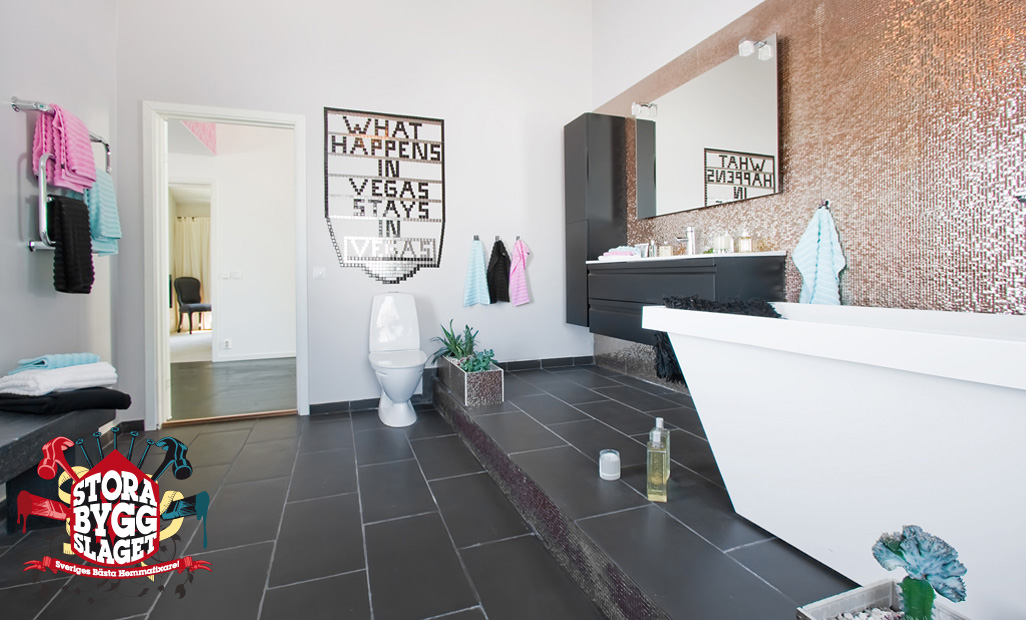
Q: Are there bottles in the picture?
A: Yes, there is a bottle.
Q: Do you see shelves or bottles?
A: Yes, there is a bottle.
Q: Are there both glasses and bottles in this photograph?
A: No, there is a bottle but no glasses.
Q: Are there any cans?
A: No, there are no cans.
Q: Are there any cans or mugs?
A: No, there are no cans or mugs.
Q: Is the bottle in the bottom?
A: Yes, the bottle is in the bottom of the image.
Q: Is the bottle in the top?
A: No, the bottle is in the bottom of the image.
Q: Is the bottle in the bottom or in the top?
A: The bottle is in the bottom of the image.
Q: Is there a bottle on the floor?
A: Yes, there is a bottle on the floor.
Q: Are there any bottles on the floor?
A: Yes, there is a bottle on the floor.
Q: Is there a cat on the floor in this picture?
A: No, there is a bottle on the floor.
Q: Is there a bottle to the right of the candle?
A: Yes, there is a bottle to the right of the candle.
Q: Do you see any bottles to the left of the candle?
A: No, the bottle is to the right of the candle.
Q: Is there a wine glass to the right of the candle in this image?
A: No, there is a bottle to the right of the candle.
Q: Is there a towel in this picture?
A: Yes, there is a towel.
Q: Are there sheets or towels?
A: Yes, there is a towel.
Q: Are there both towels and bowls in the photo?
A: Yes, there are both a towel and a bowl.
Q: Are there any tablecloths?
A: No, there are no tablecloths.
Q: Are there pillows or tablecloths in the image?
A: No, there are no tablecloths or pillows.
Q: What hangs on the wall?
A: The towel hangs on the wall.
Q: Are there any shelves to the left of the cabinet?
A: No, there is a towel to the left of the cabinet.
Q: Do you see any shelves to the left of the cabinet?
A: No, there is a towel to the left of the cabinet.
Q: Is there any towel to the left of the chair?
A: No, the towel is to the right of the chair.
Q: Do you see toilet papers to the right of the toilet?
A: No, there is a towel to the right of the toilet.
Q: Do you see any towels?
A: Yes, there is a towel.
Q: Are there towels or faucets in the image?
A: Yes, there is a towel.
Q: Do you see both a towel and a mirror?
A: Yes, there are both a towel and a mirror.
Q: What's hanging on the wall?
A: The towel is hanging on the wall.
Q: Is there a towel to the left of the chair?
A: No, the towel is to the right of the chair.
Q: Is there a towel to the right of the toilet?
A: Yes, there is a towel to the right of the toilet.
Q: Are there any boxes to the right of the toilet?
A: No, there is a towel to the right of the toilet.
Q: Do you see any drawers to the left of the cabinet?
A: No, there is a towel to the left of the cabinet.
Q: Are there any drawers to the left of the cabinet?
A: No, there is a towel to the left of the cabinet.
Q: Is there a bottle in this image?
A: Yes, there is a bottle.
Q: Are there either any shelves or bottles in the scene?
A: Yes, there is a bottle.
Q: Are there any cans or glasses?
A: No, there are no cans or glasses.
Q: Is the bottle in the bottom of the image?
A: Yes, the bottle is in the bottom of the image.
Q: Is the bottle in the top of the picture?
A: No, the bottle is in the bottom of the image.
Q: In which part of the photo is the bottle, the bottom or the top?
A: The bottle is in the bottom of the image.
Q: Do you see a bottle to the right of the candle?
A: Yes, there is a bottle to the right of the candle.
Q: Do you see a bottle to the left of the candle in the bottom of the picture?
A: No, the bottle is to the right of the candle.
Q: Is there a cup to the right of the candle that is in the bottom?
A: No, there is a bottle to the right of the candle.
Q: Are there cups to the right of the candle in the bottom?
A: No, there is a bottle to the right of the candle.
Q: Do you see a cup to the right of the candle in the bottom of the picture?
A: No, there is a bottle to the right of the candle.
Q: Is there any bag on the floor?
A: No, there is a bottle on the floor.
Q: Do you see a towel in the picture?
A: Yes, there is a towel.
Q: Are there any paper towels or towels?
A: Yes, there is a towel.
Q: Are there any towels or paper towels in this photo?
A: Yes, there is a towel.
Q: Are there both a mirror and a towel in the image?
A: Yes, there are both a towel and a mirror.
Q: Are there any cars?
A: No, there are no cars.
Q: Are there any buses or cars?
A: No, there are no cars or buses.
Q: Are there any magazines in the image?
A: No, there are no magazines.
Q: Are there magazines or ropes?
A: No, there are no magazines or ropes.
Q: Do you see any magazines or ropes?
A: No, there are no magazines or ropes.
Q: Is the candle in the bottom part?
A: Yes, the candle is in the bottom of the image.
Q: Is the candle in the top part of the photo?
A: No, the candle is in the bottom of the image.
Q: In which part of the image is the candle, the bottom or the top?
A: The candle is in the bottom of the image.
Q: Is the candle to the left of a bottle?
A: Yes, the candle is to the left of a bottle.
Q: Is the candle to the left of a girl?
A: No, the candle is to the left of a bottle.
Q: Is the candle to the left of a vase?
A: No, the candle is to the left of a bottle.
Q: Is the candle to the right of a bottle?
A: No, the candle is to the left of a bottle.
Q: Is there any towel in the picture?
A: Yes, there is a towel.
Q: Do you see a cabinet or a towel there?
A: Yes, there is a towel.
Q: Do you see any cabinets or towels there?
A: Yes, there is a towel.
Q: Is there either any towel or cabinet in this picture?
A: Yes, there is a towel.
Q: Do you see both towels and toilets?
A: Yes, there are both a towel and a toilet.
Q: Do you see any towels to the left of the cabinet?
A: Yes, there is a towel to the left of the cabinet.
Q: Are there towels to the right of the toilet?
A: Yes, there is a towel to the right of the toilet.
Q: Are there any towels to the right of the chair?
A: Yes, there is a towel to the right of the chair.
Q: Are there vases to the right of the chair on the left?
A: No, there is a towel to the right of the chair.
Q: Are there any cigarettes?
A: No, there are no cigarettes.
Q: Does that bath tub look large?
A: Yes, the bath tub is large.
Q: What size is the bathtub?
A: The bathtub is large.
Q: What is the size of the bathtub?
A: The bathtub is large.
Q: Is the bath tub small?
A: No, the bath tub is large.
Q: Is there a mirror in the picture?
A: Yes, there is a mirror.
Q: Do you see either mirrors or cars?
A: Yes, there is a mirror.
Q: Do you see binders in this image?
A: No, there are no binders.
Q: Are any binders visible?
A: No, there are no binders.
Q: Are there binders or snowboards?
A: No, there are no binders or snowboards.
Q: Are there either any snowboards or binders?
A: No, there are no binders or snowboards.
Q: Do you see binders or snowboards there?
A: No, there are no binders or snowboards.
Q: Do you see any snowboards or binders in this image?
A: No, there are no binders or snowboards.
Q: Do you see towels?
A: Yes, there is a towel.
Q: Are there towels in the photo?
A: Yes, there is a towel.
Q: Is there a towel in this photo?
A: Yes, there is a towel.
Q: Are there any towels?
A: Yes, there is a towel.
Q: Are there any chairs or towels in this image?
A: Yes, there is a towel.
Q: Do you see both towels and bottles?
A: Yes, there are both a towel and a bottle.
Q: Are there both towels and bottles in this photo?
A: Yes, there are both a towel and a bottle.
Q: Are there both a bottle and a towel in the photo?
A: Yes, there are both a towel and a bottle.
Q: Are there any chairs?
A: Yes, there is a chair.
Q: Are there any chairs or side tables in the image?
A: Yes, there is a chair.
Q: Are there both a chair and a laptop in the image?
A: No, there is a chair but no laptops.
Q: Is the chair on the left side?
A: Yes, the chair is on the left of the image.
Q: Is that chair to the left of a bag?
A: No, the chair is to the left of a towel.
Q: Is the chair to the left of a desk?
A: No, the chair is to the left of a towel.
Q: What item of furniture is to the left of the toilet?
A: The piece of furniture is a chair.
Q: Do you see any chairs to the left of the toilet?
A: Yes, there is a chair to the left of the toilet.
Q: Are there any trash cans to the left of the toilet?
A: No, there is a chair to the left of the toilet.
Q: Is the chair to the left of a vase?
A: No, the chair is to the left of a toilet.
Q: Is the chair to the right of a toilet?
A: No, the chair is to the left of a toilet.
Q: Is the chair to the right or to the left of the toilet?
A: The chair is to the left of the toilet.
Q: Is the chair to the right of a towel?
A: No, the chair is to the left of a towel.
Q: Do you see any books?
A: No, there are no books.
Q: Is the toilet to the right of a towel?
A: No, the toilet is to the left of a towel.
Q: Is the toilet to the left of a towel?
A: Yes, the toilet is to the left of a towel.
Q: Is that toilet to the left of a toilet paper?
A: No, the toilet is to the left of a towel.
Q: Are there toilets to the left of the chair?
A: No, the toilet is to the right of the chair.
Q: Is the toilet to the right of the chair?
A: Yes, the toilet is to the right of the chair.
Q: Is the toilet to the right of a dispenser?
A: No, the toilet is to the right of the chair.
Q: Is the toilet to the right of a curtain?
A: No, the toilet is to the right of the towel.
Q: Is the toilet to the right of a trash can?
A: No, the toilet is to the right of a towel.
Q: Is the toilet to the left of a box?
A: No, the toilet is to the left of a towel.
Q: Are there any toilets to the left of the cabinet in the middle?
A: Yes, there is a toilet to the left of the cabinet.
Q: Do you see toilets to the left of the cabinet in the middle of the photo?
A: Yes, there is a toilet to the left of the cabinet.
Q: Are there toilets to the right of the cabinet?
A: No, the toilet is to the left of the cabinet.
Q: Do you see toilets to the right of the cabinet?
A: No, the toilet is to the left of the cabinet.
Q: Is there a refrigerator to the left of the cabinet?
A: No, there is a toilet to the left of the cabinet.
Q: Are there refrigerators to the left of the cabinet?
A: No, there is a toilet to the left of the cabinet.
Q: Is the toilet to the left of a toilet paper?
A: No, the toilet is to the left of the cabinet.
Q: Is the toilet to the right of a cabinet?
A: No, the toilet is to the left of a cabinet.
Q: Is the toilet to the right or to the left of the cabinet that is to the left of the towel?
A: The toilet is to the left of the cabinet.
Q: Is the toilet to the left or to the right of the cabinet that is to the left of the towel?
A: The toilet is to the left of the cabinet.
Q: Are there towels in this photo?
A: Yes, there is a towel.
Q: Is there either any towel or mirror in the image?
A: Yes, there is a towel.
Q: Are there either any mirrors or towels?
A: Yes, there is a towel.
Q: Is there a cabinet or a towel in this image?
A: Yes, there is a towel.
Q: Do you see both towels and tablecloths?
A: No, there is a towel but no tablecloths.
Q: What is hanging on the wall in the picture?
A: The towel is hanging on the wall.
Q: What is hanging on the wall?
A: The towel is hanging on the wall.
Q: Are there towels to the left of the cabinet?
A: Yes, there is a towel to the left of the cabinet.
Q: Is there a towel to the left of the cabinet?
A: Yes, there is a towel to the left of the cabinet.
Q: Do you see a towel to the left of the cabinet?
A: Yes, there is a towel to the left of the cabinet.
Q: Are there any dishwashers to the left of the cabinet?
A: No, there is a towel to the left of the cabinet.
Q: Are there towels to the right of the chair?
A: Yes, there is a towel to the right of the chair.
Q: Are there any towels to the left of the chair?
A: No, the towel is to the right of the chair.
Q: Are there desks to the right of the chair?
A: No, there is a towel to the right of the chair.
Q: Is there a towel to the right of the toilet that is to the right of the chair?
A: Yes, there is a towel to the right of the toilet.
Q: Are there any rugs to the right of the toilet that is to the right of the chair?
A: No, there is a towel to the right of the toilet.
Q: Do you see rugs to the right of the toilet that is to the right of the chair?
A: No, there is a towel to the right of the toilet.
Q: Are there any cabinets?
A: Yes, there is a cabinet.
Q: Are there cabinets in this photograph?
A: Yes, there is a cabinet.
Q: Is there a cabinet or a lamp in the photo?
A: Yes, there is a cabinet.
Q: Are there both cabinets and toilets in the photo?
A: Yes, there are both a cabinet and a toilet.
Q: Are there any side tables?
A: No, there are no side tables.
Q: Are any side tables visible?
A: No, there are no side tables.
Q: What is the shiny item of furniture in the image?
A: The piece of furniture is a cabinet.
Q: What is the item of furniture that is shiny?
A: The piece of furniture is a cabinet.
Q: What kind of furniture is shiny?
A: The furniture is a cabinet.